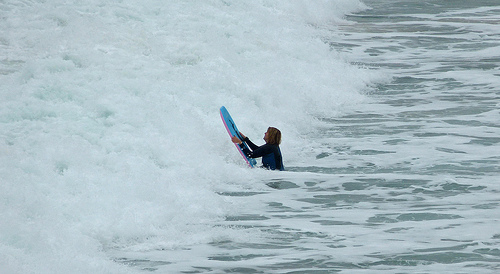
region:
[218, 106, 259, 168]
A mostly blue body board.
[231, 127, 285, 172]
A woman with blonde hair in the water.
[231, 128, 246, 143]
A woman's hands on a body board.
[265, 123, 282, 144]
Blonde hair of a woman.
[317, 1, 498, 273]
The calmer foamier water.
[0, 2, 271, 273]
A large white wave coming.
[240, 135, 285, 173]
Blue and black wetsuit.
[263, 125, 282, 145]
The head of a woman with blonde hair.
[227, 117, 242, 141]
Black design on a body board.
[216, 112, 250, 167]
Pink edge of a body board.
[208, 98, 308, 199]
surfer holding blue board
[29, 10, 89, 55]
white clouds in blue sky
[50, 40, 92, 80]
white clouds in blue sky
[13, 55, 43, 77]
white clouds in blue sky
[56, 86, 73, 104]
white clouds in blue sky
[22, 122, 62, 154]
white clouds in blue sky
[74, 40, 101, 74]
white clouds in blue sky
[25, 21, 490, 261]
A person is out in the ocean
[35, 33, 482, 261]
A person is using a surfboard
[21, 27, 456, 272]
A person is close to the beach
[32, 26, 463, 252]
A person is doing some surfing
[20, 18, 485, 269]
A person is on their vacation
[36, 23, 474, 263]
A person is wearing a wetsuit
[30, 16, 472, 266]
A person is on their day off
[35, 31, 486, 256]
A person is getting some exercise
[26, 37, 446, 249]
A person is out in the daytime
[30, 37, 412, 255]
A person is enjoying the day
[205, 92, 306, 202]
person playing in the ocean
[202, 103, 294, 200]
person going over a wave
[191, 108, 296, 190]
person getting hit by wave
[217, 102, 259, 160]
blue boogie board in hand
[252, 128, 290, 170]
woman wearing wet suit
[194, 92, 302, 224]
woman playing in the ocean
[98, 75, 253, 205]
large wave moving towards woman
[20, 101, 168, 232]
large wall of white water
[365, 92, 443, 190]
foamy white water in ocean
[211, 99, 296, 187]
boogie boarder in ocean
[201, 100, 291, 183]
The woman and her surfboard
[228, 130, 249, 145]
The hands of the woman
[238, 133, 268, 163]
The arms of the woman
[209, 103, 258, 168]
The surfboard in the water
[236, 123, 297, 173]
The woman has on a wet suit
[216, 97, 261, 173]
The surfboard is pink and blue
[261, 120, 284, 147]
The head of the woman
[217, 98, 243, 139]
The top of the surfboard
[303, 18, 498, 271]
The ocean water is blue and white